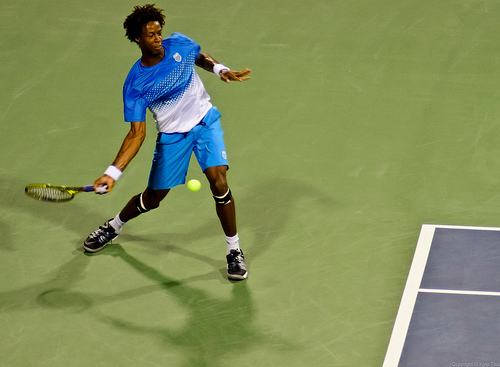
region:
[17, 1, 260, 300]
a tennis player hitting a ball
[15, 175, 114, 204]
a tennis racquet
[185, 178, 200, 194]
a bright yellow tennis ball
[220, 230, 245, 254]
the white sock on a man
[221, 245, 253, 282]
the shoe of a man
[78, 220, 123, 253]
the tennis shoe of a man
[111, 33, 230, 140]
a blue and white jersey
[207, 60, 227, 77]
a white wrist band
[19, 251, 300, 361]
the shadow of a man playing sports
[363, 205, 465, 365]
white lines of a tennis court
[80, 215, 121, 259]
the shoe of a man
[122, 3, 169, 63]
the head of a man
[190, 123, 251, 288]
the leg of a man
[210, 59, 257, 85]
the left hand of a tennis player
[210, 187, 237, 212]
the sweat band of a tennis player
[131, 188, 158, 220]
a sweatband of a tennis player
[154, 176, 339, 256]
shadow of tennis player on court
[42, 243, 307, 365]
shadow of tennis player on court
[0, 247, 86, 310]
shadow of tennis player on court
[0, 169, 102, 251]
shadow of tennis player on court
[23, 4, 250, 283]
tennis player swinging at ball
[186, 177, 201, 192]
tennis ball in the air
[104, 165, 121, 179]
white sweat band on right arm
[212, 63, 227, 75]
white sweat band on left arm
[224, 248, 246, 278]
black tennis shoe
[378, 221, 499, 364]
blue tennis court with white stripes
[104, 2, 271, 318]
This is an african american man.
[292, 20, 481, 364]
This is a concrete tennis court.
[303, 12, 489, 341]
The pavement is leveled.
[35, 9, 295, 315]
This man is a tennis player.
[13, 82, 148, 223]
The player holds the racket in his right hand.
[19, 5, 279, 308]
The player is about to hit the tennis ball.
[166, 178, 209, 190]
The tennis ball is in mid air.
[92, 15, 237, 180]
The uniform is blue and white.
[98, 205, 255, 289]
The player's shoes are black and white.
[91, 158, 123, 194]
The player is wearing white wrist bands.